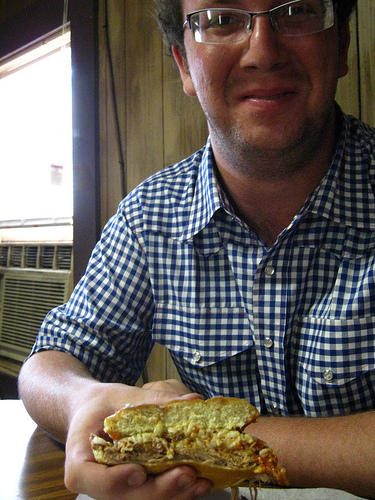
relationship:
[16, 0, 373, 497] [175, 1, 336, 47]
man wearing glasses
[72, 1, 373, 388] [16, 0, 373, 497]
wall behind man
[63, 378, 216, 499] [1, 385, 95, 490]
hand on table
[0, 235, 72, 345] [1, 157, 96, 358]
ac unit on wall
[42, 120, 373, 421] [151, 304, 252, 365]
shirt with pocket flap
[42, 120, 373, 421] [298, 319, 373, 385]
shirt with pocket flap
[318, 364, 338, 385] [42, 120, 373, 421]
button on shirt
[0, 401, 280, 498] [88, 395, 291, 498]
table beneath sandwich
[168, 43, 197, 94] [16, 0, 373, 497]
ear of man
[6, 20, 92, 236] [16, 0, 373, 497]
window behind man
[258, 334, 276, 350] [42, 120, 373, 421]
3rd button on shirt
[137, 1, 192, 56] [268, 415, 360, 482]
hair on arm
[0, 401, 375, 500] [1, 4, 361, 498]
table on room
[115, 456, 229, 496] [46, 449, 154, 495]
fingernail on finger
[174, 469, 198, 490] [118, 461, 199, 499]
fingernail on middle finger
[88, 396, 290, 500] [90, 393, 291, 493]
sandwich in hand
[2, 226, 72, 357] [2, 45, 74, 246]
air conditioner in window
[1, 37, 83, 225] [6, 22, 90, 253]
sunlight coming window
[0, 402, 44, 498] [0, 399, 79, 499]
reflected on table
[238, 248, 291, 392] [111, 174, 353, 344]
buttons on shirt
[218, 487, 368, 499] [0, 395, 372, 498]
white napkin on table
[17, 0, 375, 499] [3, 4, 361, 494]
man smiling photo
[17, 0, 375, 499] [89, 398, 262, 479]
man holding sandwich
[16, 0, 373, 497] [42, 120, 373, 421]
man wearing shirt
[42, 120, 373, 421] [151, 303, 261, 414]
shirt with pocket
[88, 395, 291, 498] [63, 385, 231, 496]
sandwich in hand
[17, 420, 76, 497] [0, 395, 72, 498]
shadow on table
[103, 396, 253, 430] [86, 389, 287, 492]
bun on sandwich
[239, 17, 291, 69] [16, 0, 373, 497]
nose of man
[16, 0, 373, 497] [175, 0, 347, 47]
man wearing eyeglasses